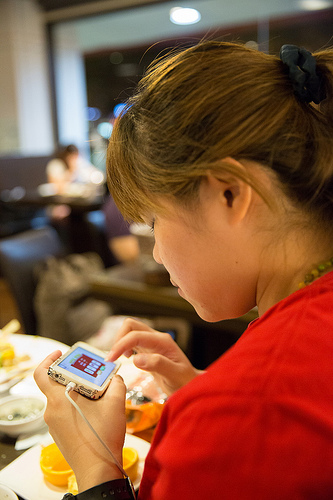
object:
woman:
[33, 30, 332, 500]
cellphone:
[47, 340, 122, 399]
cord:
[64, 382, 137, 500]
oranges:
[39, 443, 140, 495]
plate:
[0, 432, 152, 500]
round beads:
[298, 261, 332, 290]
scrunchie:
[272, 42, 333, 111]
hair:
[98, 25, 333, 283]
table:
[0, 348, 167, 500]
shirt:
[136, 267, 333, 500]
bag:
[31, 251, 113, 347]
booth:
[0, 208, 115, 334]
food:
[0, 312, 169, 498]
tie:
[280, 35, 333, 107]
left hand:
[33, 348, 132, 500]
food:
[0, 340, 30, 368]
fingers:
[104, 318, 189, 387]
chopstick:
[0, 316, 21, 343]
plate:
[0, 333, 72, 438]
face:
[139, 183, 257, 324]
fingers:
[33, 349, 62, 409]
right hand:
[104, 317, 204, 400]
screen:
[57, 345, 116, 387]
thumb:
[133, 352, 182, 385]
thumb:
[105, 374, 127, 410]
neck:
[255, 257, 333, 324]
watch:
[62, 475, 131, 498]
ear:
[207, 154, 251, 227]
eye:
[141, 215, 158, 236]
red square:
[70, 352, 106, 378]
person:
[39, 142, 106, 204]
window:
[41, 1, 333, 177]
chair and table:
[0, 223, 258, 348]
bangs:
[106, 108, 165, 227]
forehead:
[106, 121, 160, 207]